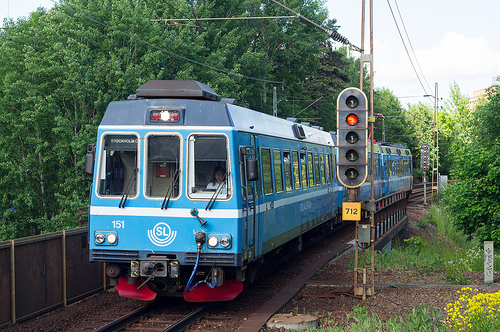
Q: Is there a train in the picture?
A: Yes, there is a train.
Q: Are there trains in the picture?
A: Yes, there is a train.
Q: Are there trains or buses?
A: Yes, there is a train.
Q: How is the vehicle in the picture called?
A: The vehicle is a train.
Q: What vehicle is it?
A: The vehicle is a train.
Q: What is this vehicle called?
A: This is a train.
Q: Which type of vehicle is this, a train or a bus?
A: This is a train.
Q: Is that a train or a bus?
A: That is a train.